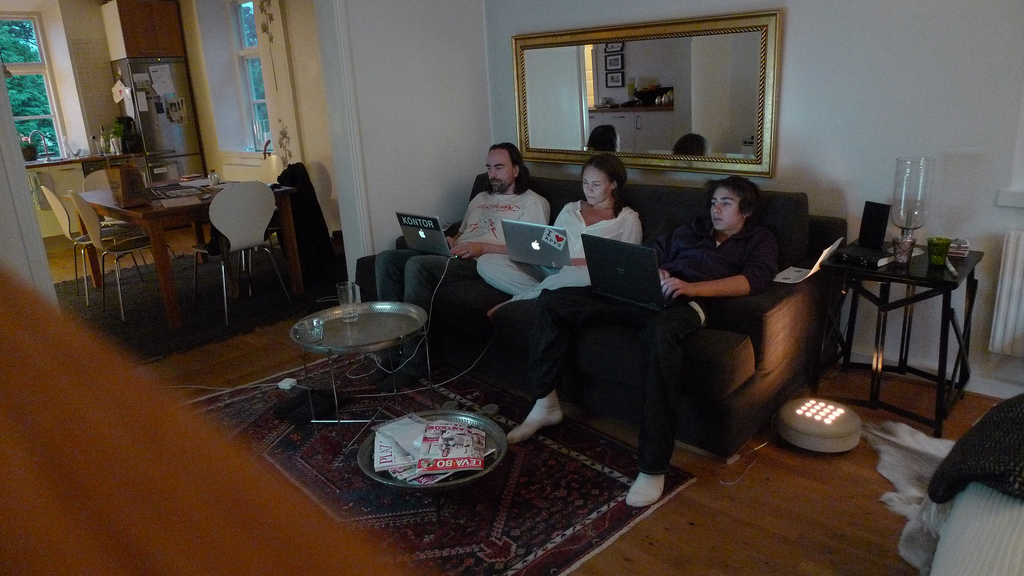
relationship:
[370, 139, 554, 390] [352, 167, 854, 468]
man sitting on couch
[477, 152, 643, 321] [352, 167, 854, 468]
person sitting on couch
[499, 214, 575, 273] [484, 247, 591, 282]
laptop placed on lap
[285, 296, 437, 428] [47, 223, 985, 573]
table standing on floor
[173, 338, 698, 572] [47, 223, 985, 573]
rug lying on floor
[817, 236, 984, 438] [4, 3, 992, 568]
table standing in room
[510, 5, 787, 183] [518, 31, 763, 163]
frame surrounding mirror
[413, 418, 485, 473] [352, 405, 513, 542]
magazine lying on top of table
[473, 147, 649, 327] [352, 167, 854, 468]
person sitting on couch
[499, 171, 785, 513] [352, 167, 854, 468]
person sitting on couch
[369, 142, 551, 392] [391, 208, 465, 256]
man using laptop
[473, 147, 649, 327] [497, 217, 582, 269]
person using laptop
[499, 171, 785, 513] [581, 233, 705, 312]
person using computer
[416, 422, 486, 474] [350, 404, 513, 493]
magazine lying on top of tray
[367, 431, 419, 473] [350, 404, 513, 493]
magazine lying on top of tray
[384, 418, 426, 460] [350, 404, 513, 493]
magazine lying on top of tray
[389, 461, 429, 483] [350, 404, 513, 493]
magazine lying on top of tray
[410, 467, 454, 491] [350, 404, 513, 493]
magazine lying on top of tray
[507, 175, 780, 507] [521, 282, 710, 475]
person wearing pants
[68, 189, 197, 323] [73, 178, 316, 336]
chair sitting at table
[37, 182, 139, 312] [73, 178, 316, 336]
chair sitting at table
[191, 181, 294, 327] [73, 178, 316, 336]
chair sitting at table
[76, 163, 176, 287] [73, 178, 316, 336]
chair sitting at table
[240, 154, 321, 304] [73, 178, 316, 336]
chair sitting at table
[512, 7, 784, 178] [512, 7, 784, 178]
frame surrounding frame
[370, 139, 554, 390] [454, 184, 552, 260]
man wearing shirt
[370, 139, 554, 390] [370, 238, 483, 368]
man wearing jeans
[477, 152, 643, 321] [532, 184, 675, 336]
person with clothing